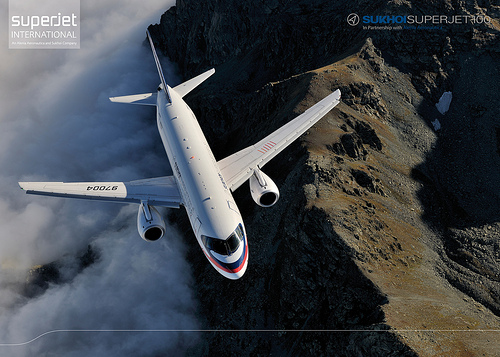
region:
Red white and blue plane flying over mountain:
[23, 46, 359, 283]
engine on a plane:
[236, 163, 301, 220]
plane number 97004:
[78, 171, 150, 234]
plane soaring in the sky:
[108, 44, 266, 288]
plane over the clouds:
[33, 95, 315, 216]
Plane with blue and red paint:
[191, 241, 265, 281]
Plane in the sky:
[98, 63, 295, 243]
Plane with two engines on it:
[116, 179, 298, 239]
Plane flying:
[108, 178, 323, 249]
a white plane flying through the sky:
[18, 63, 364, 274]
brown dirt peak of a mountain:
[309, 213, 426, 314]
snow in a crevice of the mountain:
[413, 80, 471, 143]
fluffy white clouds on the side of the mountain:
[26, 230, 169, 317]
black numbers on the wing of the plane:
[76, 179, 128, 200]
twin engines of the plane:
[121, 162, 284, 239]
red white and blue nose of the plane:
[206, 240, 252, 280]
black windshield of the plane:
[196, 218, 248, 262]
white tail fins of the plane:
[107, 39, 204, 114]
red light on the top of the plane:
[186, 151, 201, 163]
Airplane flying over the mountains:
[85, 43, 332, 279]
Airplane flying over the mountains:
[118, 150, 313, 297]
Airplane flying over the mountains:
[23, 116, 368, 257]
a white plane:
[4, 25, 413, 302]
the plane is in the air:
[4, 20, 382, 311]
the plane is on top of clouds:
[19, 19, 370, 290]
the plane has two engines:
[82, 155, 291, 269]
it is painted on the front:
[167, 245, 264, 266]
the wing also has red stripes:
[242, 135, 297, 156]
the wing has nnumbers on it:
[62, 173, 136, 210]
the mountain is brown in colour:
[263, 64, 408, 354]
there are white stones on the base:
[349, 65, 475, 140]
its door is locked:
[191, 211, 203, 231]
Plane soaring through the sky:
[41, 63, 271, 266]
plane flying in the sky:
[151, 174, 324, 306]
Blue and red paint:
[188, 238, 257, 295]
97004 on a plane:
[78, 175, 129, 208]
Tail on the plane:
[108, 40, 208, 105]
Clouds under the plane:
[19, 74, 135, 212]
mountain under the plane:
[303, 139, 425, 307]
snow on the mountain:
[424, 80, 479, 140]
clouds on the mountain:
[89, 249, 191, 310]